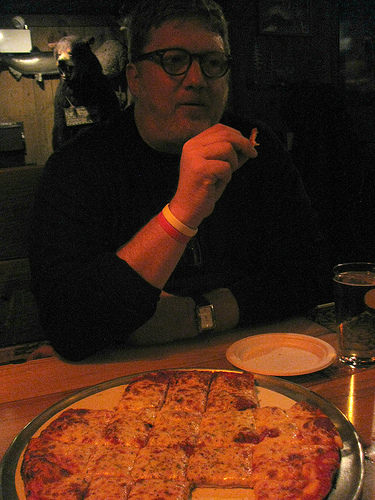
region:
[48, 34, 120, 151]
the bear in the background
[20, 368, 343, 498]
the pizza on the platter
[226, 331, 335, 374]
the empty plate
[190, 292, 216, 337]
the watch on the man's arm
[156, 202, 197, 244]
the bracelet's on the man's arm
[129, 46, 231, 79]
the glasses on the man's face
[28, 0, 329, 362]
the man sitting down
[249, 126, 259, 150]
the food in the man's hand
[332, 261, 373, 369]
the cup on the table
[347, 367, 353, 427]
the light reflected on the table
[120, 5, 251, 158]
head of a person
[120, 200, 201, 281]
arm of a person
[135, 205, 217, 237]
wrist of a person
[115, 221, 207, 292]
an arm of a person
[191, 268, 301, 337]
an arm of a person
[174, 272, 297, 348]
arm of a person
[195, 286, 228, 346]
wrist of a person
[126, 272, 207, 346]
hand of a person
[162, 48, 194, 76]
eye of a person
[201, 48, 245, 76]
eye of a person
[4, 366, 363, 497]
Snacks on a tray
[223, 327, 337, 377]
Small round brown plate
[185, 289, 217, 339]
Watch on a wrist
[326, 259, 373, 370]
Tall glass with liquid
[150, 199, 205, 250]
Pair of wrist bands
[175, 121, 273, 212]
Hand holding a piece of food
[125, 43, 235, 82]
Black rimmed colorless glasses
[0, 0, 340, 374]
Man leaning on a table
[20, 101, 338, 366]
Black long sleeved shirt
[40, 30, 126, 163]
Bust of a black bear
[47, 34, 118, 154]
A stuffed bear behind the man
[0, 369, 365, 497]
A silver tray on the table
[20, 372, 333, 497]
A pizza on the silver tray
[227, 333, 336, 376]
A paper plate on the table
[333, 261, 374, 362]
A glass full of a beverage on the table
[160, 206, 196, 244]
Red and yellow bands on the man's hand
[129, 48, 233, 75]
The man is wearing glasses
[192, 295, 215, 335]
The man is wearing a watch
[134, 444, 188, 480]
A square slice of the pizza